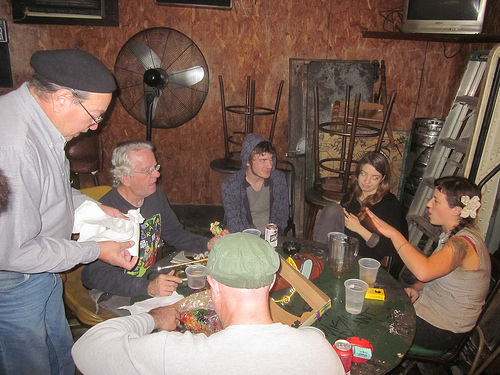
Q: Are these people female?
A: No, they are both male and female.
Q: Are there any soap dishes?
A: No, there are no soap dishes.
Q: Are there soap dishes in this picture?
A: No, there are no soap dishes.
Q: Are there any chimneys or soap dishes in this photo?
A: No, there are no soap dishes or chimneys.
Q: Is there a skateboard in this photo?
A: No, there are no skateboards.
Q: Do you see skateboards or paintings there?
A: No, there are no skateboards or paintings.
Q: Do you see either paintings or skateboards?
A: No, there are no skateboards or paintings.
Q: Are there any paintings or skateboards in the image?
A: No, there are no skateboards or paintings.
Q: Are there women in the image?
A: Yes, there is a woman.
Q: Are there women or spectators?
A: Yes, there is a woman.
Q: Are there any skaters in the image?
A: No, there are no skaters.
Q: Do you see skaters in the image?
A: No, there are no skaters.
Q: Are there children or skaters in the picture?
A: No, there are no skaters or children.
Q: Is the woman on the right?
A: Yes, the woman is on the right of the image.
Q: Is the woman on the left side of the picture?
A: No, the woman is on the right of the image.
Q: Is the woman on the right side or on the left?
A: The woman is on the right of the image.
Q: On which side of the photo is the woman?
A: The woman is on the right of the image.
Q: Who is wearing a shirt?
A: The woman is wearing a shirt.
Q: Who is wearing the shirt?
A: The woman is wearing a shirt.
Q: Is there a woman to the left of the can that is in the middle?
A: No, the woman is to the right of the can.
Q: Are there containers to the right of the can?
A: No, there is a woman to the right of the can.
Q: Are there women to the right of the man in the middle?
A: Yes, there is a woman to the right of the man.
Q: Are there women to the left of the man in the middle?
A: No, the woman is to the right of the man.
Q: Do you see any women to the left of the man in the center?
A: No, the woman is to the right of the man.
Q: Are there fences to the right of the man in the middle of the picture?
A: No, there is a woman to the right of the man.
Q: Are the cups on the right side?
A: Yes, the cups are on the right of the image.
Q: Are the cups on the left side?
A: No, the cups are on the right of the image.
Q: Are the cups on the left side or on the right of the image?
A: The cups are on the right of the image.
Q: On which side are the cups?
A: The cups are on the right of the image.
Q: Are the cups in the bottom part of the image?
A: Yes, the cups are in the bottom of the image.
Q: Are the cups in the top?
A: No, the cups are in the bottom of the image.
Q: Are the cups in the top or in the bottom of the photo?
A: The cups are in the bottom of the image.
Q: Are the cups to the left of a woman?
A: Yes, the cups are to the left of a woman.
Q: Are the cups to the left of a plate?
A: No, the cups are to the left of a woman.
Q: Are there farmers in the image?
A: No, there are no farmers.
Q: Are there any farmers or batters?
A: No, there are no farmers or batters.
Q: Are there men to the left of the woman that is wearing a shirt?
A: Yes, there is a man to the left of the woman.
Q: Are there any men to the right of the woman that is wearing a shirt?
A: No, the man is to the left of the woman.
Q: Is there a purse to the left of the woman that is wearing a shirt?
A: No, there is a man to the left of the woman.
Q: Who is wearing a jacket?
A: The man is wearing a jacket.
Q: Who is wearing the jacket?
A: The man is wearing a jacket.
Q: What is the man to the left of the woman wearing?
A: The man is wearing a jacket.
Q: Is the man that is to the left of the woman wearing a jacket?
A: Yes, the man is wearing a jacket.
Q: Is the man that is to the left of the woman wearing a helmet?
A: No, the man is wearing a jacket.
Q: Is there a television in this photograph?
A: Yes, there is a television.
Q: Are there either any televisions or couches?
A: Yes, there is a television.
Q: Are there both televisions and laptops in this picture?
A: No, there is a television but no laptops.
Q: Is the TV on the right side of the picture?
A: Yes, the TV is on the right of the image.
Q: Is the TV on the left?
A: No, the TV is on the right of the image.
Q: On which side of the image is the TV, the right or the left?
A: The TV is on the right of the image.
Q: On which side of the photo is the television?
A: The television is on the right of the image.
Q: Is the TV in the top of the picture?
A: Yes, the TV is in the top of the image.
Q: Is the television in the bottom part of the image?
A: No, the television is in the top of the image.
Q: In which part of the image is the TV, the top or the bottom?
A: The TV is in the top of the image.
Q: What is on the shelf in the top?
A: The television is on the shelf.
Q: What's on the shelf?
A: The television is on the shelf.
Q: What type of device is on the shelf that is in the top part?
A: The device is a television.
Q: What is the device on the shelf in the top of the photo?
A: The device is a television.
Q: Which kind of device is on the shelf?
A: The device is a television.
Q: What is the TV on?
A: The TV is on the shelf.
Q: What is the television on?
A: The TV is on the shelf.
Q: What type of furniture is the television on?
A: The television is on the shelf.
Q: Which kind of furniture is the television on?
A: The television is on the shelf.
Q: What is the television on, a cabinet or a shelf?
A: The television is on a shelf.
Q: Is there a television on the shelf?
A: Yes, there is a television on the shelf.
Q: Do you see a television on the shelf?
A: Yes, there is a television on the shelf.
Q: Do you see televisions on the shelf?
A: Yes, there is a television on the shelf.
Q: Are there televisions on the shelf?
A: Yes, there is a television on the shelf.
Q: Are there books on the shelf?
A: No, there is a television on the shelf.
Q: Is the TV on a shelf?
A: Yes, the TV is on a shelf.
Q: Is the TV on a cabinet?
A: No, the TV is on a shelf.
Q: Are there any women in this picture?
A: Yes, there is a woman.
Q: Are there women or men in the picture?
A: Yes, there is a woman.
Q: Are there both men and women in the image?
A: Yes, there are both a woman and a man.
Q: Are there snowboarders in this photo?
A: No, there are no snowboarders.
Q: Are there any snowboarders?
A: No, there are no snowboarders.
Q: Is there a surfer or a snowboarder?
A: No, there are no snowboarders or surfers.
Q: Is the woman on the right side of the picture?
A: Yes, the woman is on the right of the image.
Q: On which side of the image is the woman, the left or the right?
A: The woman is on the right of the image.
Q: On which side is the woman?
A: The woman is on the right of the image.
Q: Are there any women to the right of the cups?
A: Yes, there is a woman to the right of the cups.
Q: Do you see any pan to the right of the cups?
A: No, there is a woman to the right of the cups.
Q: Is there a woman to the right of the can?
A: Yes, there is a woman to the right of the can.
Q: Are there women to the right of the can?
A: Yes, there is a woman to the right of the can.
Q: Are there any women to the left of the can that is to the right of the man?
A: No, the woman is to the right of the can.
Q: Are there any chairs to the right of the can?
A: No, there is a woman to the right of the can.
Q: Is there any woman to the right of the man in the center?
A: Yes, there is a woman to the right of the man.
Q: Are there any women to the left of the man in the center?
A: No, the woman is to the right of the man.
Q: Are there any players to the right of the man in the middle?
A: No, there is a woman to the right of the man.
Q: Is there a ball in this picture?
A: No, there are no balls.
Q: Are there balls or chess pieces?
A: No, there are no balls or chess pieces.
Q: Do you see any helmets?
A: No, there are no helmets.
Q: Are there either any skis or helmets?
A: No, there are no helmets or skis.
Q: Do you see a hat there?
A: Yes, there is a hat.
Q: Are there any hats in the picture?
A: Yes, there is a hat.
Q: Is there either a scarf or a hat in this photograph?
A: Yes, there is a hat.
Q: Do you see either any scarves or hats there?
A: Yes, there is a hat.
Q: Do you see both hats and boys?
A: No, there is a hat but no boys.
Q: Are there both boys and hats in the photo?
A: No, there is a hat but no boys.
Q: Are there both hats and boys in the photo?
A: No, there is a hat but no boys.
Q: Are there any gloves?
A: No, there are no gloves.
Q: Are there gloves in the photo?
A: No, there are no gloves.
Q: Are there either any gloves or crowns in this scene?
A: No, there are no gloves or crowns.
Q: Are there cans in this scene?
A: Yes, there is a can.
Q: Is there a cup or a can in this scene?
A: Yes, there is a can.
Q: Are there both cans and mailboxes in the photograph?
A: No, there is a can but no mailboxes.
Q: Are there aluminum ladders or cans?
A: Yes, there is an aluminum can.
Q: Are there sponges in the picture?
A: No, there are no sponges.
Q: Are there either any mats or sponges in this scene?
A: No, there are no sponges or mats.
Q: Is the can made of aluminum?
A: Yes, the can is made of aluminum.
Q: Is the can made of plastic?
A: No, the can is made of aluminum.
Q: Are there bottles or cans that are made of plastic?
A: No, there is a can but it is made of aluminum.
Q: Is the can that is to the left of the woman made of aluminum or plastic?
A: The can is made of aluminum.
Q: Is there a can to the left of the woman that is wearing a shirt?
A: Yes, there is a can to the left of the woman.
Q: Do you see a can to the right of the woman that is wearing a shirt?
A: No, the can is to the left of the woman.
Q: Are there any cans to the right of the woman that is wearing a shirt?
A: No, the can is to the left of the woman.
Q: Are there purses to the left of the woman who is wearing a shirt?
A: No, there is a can to the left of the woman.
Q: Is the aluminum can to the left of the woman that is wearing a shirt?
A: Yes, the can is to the left of the woman.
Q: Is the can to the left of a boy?
A: No, the can is to the left of the woman.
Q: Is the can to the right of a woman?
A: No, the can is to the left of a woman.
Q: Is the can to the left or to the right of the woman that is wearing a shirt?
A: The can is to the left of the woman.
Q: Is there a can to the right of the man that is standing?
A: Yes, there is a can to the right of the man.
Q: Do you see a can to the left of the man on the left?
A: No, the can is to the right of the man.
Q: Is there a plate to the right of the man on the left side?
A: No, there is a can to the right of the man.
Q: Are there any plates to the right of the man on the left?
A: No, there is a can to the right of the man.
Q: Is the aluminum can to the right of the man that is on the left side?
A: Yes, the can is to the right of the man.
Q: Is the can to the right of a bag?
A: No, the can is to the right of the man.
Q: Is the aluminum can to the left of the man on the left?
A: No, the can is to the right of the man.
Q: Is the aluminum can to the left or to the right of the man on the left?
A: The can is to the right of the man.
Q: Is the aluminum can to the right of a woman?
A: No, the can is to the left of a woman.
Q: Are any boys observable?
A: No, there are no boys.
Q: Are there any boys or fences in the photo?
A: No, there are no boys or fences.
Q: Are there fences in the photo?
A: No, there are no fences.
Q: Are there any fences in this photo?
A: No, there are no fences.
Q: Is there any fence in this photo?
A: No, there are no fences.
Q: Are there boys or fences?
A: No, there are no fences or boys.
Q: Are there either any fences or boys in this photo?
A: No, there are no fences or boys.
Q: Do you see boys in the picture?
A: No, there are no boys.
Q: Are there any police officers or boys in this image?
A: No, there are no boys or police officers.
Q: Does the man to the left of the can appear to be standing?
A: Yes, the man is standing.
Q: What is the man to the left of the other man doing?
A: The man is standing.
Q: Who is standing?
A: The man is standing.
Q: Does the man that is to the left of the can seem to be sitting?
A: No, the man is standing.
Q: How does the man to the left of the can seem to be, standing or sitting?
A: The man is standing.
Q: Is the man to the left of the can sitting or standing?
A: The man is standing.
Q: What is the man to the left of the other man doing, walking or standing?
A: The man is standing.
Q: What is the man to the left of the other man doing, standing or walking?
A: The man is standing.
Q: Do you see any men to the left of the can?
A: Yes, there is a man to the left of the can.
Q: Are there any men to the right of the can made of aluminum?
A: No, the man is to the left of the can.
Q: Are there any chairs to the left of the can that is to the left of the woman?
A: No, there is a man to the left of the can.